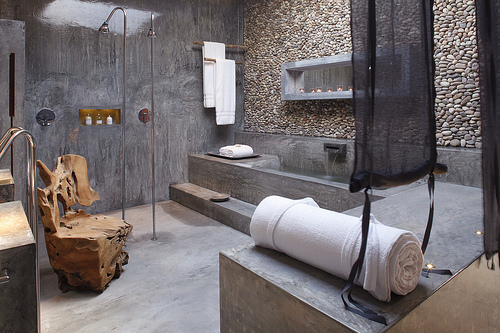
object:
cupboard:
[214, 181, 497, 333]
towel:
[214, 59, 238, 126]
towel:
[201, 40, 226, 108]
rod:
[193, 40, 249, 64]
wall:
[242, 0, 500, 151]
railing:
[1, 125, 40, 333]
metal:
[96, 6, 127, 223]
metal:
[145, 13, 157, 244]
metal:
[149, 129, 156, 239]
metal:
[121, 124, 126, 222]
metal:
[0, 126, 41, 333]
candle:
[299, 88, 306, 94]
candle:
[310, 88, 316, 94]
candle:
[316, 87, 322, 94]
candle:
[327, 87, 333, 92]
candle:
[336, 85, 343, 92]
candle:
[347, 85, 354, 91]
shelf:
[280, 43, 420, 99]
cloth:
[343, 0, 442, 193]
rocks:
[433, 0, 477, 148]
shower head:
[146, 9, 157, 242]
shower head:
[98, 6, 127, 241]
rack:
[204, 57, 244, 65]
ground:
[29, 200, 252, 333]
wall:
[0, 0, 242, 225]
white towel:
[245, 194, 425, 302]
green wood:
[200, 38, 239, 128]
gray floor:
[36, 200, 248, 333]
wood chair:
[33, 153, 133, 296]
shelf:
[78, 107, 120, 126]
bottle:
[106, 113, 112, 124]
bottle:
[95, 113, 103, 126]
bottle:
[85, 113, 93, 125]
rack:
[204, 56, 244, 65]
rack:
[193, 39, 248, 50]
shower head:
[95, 7, 127, 226]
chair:
[35, 153, 133, 293]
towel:
[218, 144, 253, 157]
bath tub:
[188, 152, 431, 212]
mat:
[247, 193, 433, 299]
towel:
[201, 40, 236, 126]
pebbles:
[441, 53, 478, 98]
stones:
[465, 61, 477, 73]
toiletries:
[85, 112, 113, 125]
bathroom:
[0, 0, 499, 332]